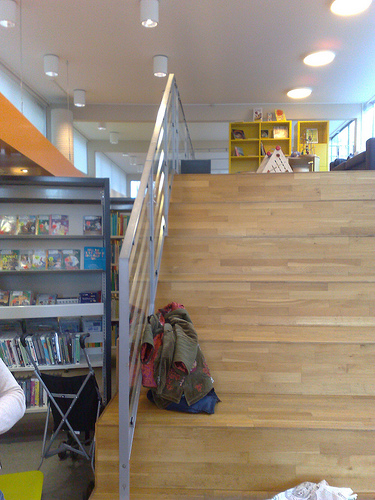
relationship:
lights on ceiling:
[287, 0, 372, 101] [2, 0, 373, 174]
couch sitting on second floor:
[331, 141, 373, 168] [176, 103, 373, 175]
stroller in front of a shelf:
[19, 332, 100, 475] [4, 165, 112, 418]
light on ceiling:
[297, 39, 343, 73] [8, 3, 362, 155]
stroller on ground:
[19, 332, 94, 419] [13, 447, 25, 466]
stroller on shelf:
[19, 332, 94, 419] [4, 165, 112, 418]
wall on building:
[35, 133, 122, 385] [3, 4, 362, 483]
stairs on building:
[87, 164, 375, 498] [3, 4, 362, 483]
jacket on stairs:
[157, 296, 204, 385] [121, 121, 357, 481]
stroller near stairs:
[19, 332, 94, 419] [148, 127, 355, 455]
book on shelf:
[5, 242, 26, 268] [5, 236, 122, 285]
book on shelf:
[45, 247, 79, 269] [0, 239, 118, 274]